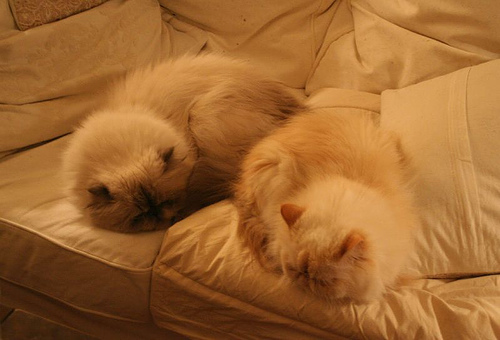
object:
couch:
[0, 0, 495, 337]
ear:
[82, 179, 110, 208]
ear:
[157, 144, 184, 170]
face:
[87, 168, 185, 234]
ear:
[340, 232, 366, 260]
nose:
[153, 210, 166, 229]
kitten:
[60, 43, 309, 235]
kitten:
[222, 96, 428, 307]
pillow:
[375, 57, 500, 281]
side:
[383, 2, 498, 334]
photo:
[0, 0, 499, 340]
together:
[58, 50, 430, 306]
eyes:
[128, 213, 146, 223]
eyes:
[286, 259, 296, 272]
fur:
[266, 124, 399, 208]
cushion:
[149, 197, 500, 340]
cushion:
[0, 126, 170, 325]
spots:
[444, 296, 481, 319]